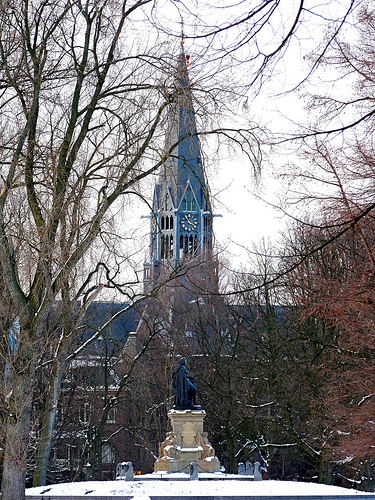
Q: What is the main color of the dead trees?
A: Brown.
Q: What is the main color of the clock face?
A: Blue.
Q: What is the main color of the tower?
A: Blue.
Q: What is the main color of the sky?
A: White.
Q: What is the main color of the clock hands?
A: Yellow.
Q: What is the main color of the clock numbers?
A: Yellow.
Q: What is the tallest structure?
A: The clock tower.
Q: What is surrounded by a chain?
A: A statue.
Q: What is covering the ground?
A: Snow.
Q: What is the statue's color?
A: Black.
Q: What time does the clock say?
A: 3:55.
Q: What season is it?
A: Winter.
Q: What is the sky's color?
A: Grey.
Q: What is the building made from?
A: Bricks.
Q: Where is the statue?
A: In front of the building.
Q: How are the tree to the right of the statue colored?
A: Orange.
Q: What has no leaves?
A: The tree.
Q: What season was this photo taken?
A: Winter.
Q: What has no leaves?
A: The tree.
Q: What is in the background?
A: A clock tower.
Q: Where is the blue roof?
A: On the clock tower.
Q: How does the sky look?
A: White with clouds.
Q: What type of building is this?
A: Church.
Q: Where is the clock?
A: Steeple.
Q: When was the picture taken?
A: Winter.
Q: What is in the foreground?
A: Trees.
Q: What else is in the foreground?
A: Monument.